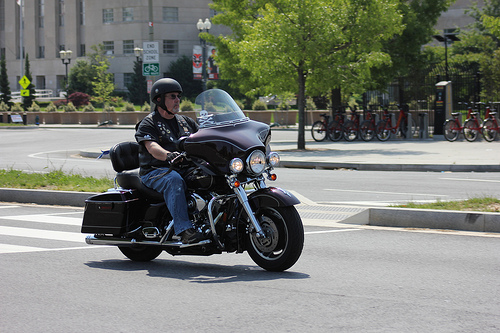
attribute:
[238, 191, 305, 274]
wheel — black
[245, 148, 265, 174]
light — white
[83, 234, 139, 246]
muffler — silver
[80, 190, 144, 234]
carrying case — black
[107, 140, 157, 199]
seat — black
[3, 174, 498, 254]
crosswalk — white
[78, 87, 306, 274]
motorcycle — large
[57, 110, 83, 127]
planter container — large, brown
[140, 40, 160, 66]
street sign — black, white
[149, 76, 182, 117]
helmet — black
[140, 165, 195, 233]
jeans — blue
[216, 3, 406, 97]
leaves — green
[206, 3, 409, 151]
tree — large, green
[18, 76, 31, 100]
signs — neon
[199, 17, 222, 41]
lights — STREET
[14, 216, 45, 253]
lines — BLOCK, WHITE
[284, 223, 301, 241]
tire — BIKE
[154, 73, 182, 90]
helmet — BLACK